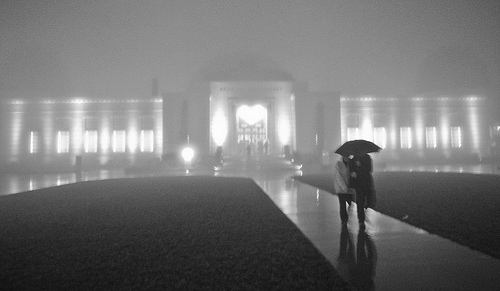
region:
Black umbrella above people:
[333, 138, 381, 153]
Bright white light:
[176, 147, 196, 164]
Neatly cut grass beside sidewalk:
[17, 170, 317, 283]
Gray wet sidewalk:
[270, 175, 340, 223]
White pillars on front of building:
[8, 98, 170, 173]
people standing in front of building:
[245, 135, 272, 159]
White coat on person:
[333, 156, 348, 196]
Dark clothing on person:
[355, 157, 375, 231]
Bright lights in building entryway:
[235, 98, 267, 131]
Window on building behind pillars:
[139, 126, 154, 155]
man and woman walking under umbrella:
[327, 132, 389, 234]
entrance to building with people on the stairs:
[227, 101, 277, 159]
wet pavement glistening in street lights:
[266, 174, 321, 224]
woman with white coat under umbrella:
[332, 152, 356, 228]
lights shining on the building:
[406, 102, 436, 172]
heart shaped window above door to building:
[233, 100, 273, 142]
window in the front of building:
[396, 125, 413, 150]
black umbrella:
[331, 132, 383, 164]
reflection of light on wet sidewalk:
[272, 179, 312, 221]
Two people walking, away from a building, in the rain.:
[6, 18, 492, 273]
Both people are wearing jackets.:
[330, 137, 382, 232]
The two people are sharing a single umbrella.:
[326, 140, 381, 240]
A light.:
[175, 131, 200, 173]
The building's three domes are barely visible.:
[5, 25, 490, 90]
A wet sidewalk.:
[255, 175, 495, 282]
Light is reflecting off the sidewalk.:
[251, 166, 321, 221]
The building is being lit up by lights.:
[6, 82, 492, 157]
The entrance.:
[225, 90, 280, 157]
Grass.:
[75, 181, 225, 277]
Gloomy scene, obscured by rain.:
[3, 13, 499, 288]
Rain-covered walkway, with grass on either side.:
[16, 169, 491, 289]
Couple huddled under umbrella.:
[333, 142, 383, 247]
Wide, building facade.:
[16, 73, 476, 179]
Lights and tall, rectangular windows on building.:
[6, 95, 173, 164]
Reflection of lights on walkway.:
[16, 168, 139, 188]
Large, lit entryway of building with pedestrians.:
[213, 83, 299, 176]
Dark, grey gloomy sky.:
[18, 12, 460, 52]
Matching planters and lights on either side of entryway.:
[193, 136, 307, 178]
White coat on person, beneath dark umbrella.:
[328, 157, 355, 202]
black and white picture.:
[29, 45, 479, 233]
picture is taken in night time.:
[13, 26, 469, 258]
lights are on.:
[28, 114, 474, 184]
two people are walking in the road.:
[333, 123, 390, 238]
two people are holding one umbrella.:
[339, 136, 382, 221]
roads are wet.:
[275, 181, 412, 289]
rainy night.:
[38, 47, 479, 280]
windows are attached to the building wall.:
[13, 111, 485, 172]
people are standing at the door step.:
[233, 128, 287, 169]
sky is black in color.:
[37, 15, 335, 69]